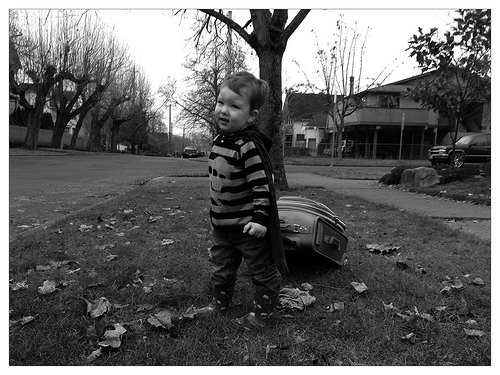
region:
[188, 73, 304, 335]
young boy standing in the grass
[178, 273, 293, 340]
small rubber boots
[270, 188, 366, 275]
small suitcase on wheels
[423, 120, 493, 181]
SUV parked along the side of the road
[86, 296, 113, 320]
crumpled leave laying in the grass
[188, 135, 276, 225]
striped long sleeve sweater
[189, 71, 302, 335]
little boy wearing a cape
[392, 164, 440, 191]
boulder in the grass next the the sidewalk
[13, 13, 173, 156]
trees lining the street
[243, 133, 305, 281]
long, dark cape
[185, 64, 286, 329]
this is a child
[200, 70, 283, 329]
the boy is standing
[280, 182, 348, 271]
this is a suitcase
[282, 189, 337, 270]
the suitcase is big in size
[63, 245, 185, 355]
the leaves are on the ground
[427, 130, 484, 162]
this is a car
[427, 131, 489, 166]
the car is parked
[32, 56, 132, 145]
the trees are dry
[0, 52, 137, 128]
the trees are in a row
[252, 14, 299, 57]
the tree is behind the boy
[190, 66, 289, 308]
black and white photo of a toddler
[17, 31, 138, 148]
a row of leafless trees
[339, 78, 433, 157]
a house with an upper deck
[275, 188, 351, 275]
a suite case being pulled by a toddler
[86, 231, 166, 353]
large fallen leaves in the grass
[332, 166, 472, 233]
a suburban side walk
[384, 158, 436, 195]
large stones on the corner of the block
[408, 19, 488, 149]
a small tree with large leaves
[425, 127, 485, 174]
a black truck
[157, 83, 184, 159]
a telephone pole in the distance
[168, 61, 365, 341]
Little boy in a costume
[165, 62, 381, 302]
Littel boy pulling suitcase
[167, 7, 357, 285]
Bare tree behind little boy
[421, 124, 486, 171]
Truck parked by curb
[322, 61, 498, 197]
Truck in front of house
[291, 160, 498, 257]
Sidewalk is empty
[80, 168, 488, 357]
leaves are on the ground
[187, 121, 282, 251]
Skull on little boy's shirt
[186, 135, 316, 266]
Shirt is striped with skull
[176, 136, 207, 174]
Cars parked in the distance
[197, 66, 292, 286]
this is a baby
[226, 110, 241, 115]
the baby is light skinned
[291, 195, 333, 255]
this is bag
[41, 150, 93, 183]
this is the road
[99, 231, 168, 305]
this is a grass area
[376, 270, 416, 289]
the grass is green in color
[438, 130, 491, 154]
this is a car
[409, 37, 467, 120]
this is the tree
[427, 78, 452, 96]
the tree has green leaves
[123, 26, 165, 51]
this is the sky